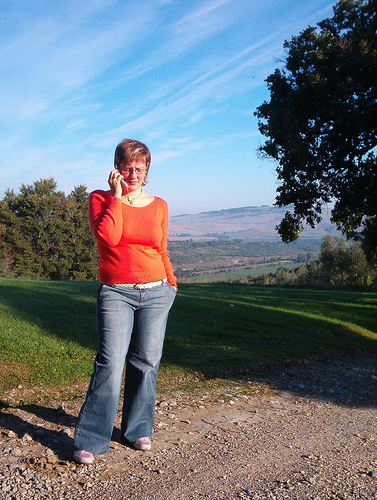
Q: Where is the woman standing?
A: On the gravel path.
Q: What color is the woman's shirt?
A: Orange.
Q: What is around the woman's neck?
A: A necklace.